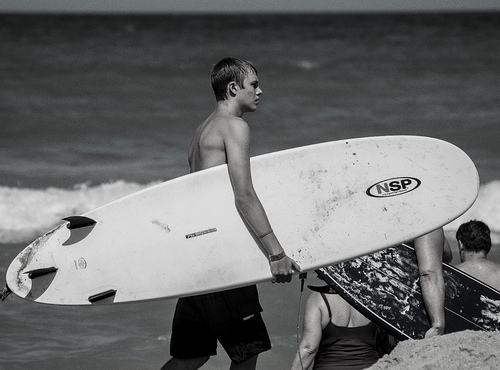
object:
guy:
[156, 57, 301, 368]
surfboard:
[5, 134, 480, 306]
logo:
[366, 176, 421, 198]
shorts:
[170, 283, 273, 363]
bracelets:
[267, 250, 287, 262]